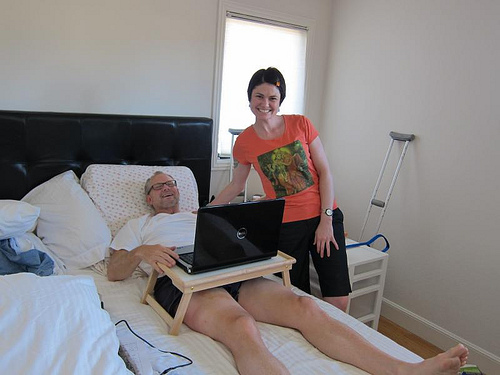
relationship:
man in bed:
[101, 158, 425, 375] [12, 163, 429, 375]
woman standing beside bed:
[215, 59, 363, 313] [12, 163, 429, 375]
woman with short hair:
[215, 59, 363, 313] [242, 66, 287, 102]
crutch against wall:
[348, 123, 415, 246] [336, 39, 500, 168]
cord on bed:
[98, 293, 191, 374] [12, 163, 429, 375]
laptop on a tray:
[156, 191, 286, 271] [153, 259, 298, 309]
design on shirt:
[251, 139, 320, 209] [209, 99, 344, 238]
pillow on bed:
[0, 155, 203, 268] [12, 163, 429, 375]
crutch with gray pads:
[348, 123, 415, 246] [387, 127, 417, 146]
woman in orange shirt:
[215, 59, 363, 313] [209, 99, 344, 238]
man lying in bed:
[101, 158, 425, 375] [12, 163, 429, 375]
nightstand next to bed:
[308, 229, 389, 336] [12, 163, 429, 375]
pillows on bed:
[17, 163, 119, 254] [12, 163, 429, 375]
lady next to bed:
[215, 59, 363, 313] [12, 163, 429, 375]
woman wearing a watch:
[215, 59, 363, 313] [317, 202, 337, 218]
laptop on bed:
[156, 191, 286, 271] [12, 163, 429, 375]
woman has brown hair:
[215, 59, 363, 313] [243, 66, 287, 107]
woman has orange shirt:
[215, 59, 363, 313] [236, 123, 314, 159]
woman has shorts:
[215, 59, 363, 313] [269, 212, 355, 303]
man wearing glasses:
[101, 158, 425, 375] [147, 175, 179, 192]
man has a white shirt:
[101, 158, 425, 375] [131, 214, 197, 246]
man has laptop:
[101, 158, 425, 375] [156, 191, 286, 271]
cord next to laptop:
[98, 293, 191, 374] [156, 191, 286, 271]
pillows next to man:
[17, 163, 119, 254] [101, 158, 425, 375]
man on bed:
[101, 158, 425, 375] [12, 163, 429, 375]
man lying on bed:
[101, 158, 425, 375] [12, 163, 429, 375]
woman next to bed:
[215, 59, 363, 313] [12, 163, 429, 375]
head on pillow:
[142, 168, 183, 211] [0, 155, 203, 268]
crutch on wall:
[348, 123, 415, 246] [336, 39, 500, 168]